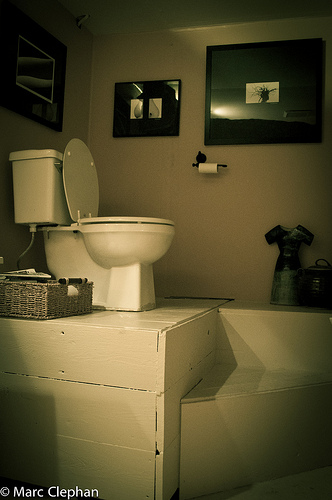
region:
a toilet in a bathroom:
[5, 7, 315, 498]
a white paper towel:
[194, 160, 220, 176]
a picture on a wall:
[201, 34, 330, 149]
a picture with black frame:
[196, 35, 330, 150]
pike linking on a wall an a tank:
[0, 214, 44, 271]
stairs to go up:
[52, 148, 328, 498]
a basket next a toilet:
[0, 247, 111, 324]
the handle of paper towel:
[186, 151, 230, 175]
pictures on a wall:
[88, 24, 325, 209]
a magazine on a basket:
[0, 259, 95, 321]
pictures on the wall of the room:
[101, 36, 322, 154]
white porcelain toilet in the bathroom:
[1, 138, 165, 324]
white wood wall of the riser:
[53, 347, 142, 461]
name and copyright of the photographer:
[0, 483, 108, 499]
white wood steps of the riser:
[182, 296, 304, 475]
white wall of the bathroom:
[197, 196, 242, 254]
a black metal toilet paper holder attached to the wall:
[188, 149, 234, 182]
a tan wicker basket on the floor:
[1, 270, 96, 313]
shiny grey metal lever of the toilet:
[51, 156, 62, 174]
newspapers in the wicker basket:
[1, 269, 70, 288]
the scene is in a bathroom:
[31, 40, 330, 495]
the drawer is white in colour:
[4, 320, 133, 497]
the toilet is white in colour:
[73, 169, 184, 319]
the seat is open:
[25, 121, 175, 262]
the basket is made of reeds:
[4, 266, 101, 320]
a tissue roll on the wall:
[175, 148, 238, 186]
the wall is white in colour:
[172, 230, 236, 285]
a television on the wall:
[207, 36, 330, 160]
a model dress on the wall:
[234, 203, 314, 282]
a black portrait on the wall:
[106, 56, 191, 160]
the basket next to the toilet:
[1, 271, 93, 319]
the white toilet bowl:
[8, 137, 174, 312]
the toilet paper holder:
[191, 150, 227, 174]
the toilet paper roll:
[198, 163, 218, 174]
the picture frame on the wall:
[204, 39, 326, 148]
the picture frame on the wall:
[111, 76, 180, 136]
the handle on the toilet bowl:
[53, 160, 62, 173]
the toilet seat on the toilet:
[77, 216, 173, 225]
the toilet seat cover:
[61, 137, 99, 221]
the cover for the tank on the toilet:
[8, 149, 63, 161]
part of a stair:
[276, 422, 287, 433]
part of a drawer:
[106, 421, 110, 423]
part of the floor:
[136, 470, 146, 473]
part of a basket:
[44, 309, 50, 312]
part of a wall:
[176, 433, 186, 449]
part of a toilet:
[124, 263, 137, 276]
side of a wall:
[113, 430, 130, 454]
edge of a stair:
[109, 402, 118, 410]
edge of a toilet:
[145, 285, 150, 291]